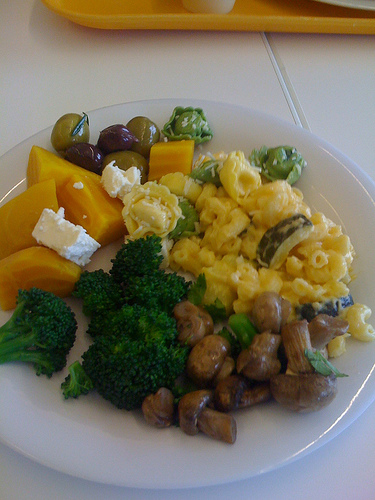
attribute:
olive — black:
[98, 126, 138, 155]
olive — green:
[52, 114, 90, 150]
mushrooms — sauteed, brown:
[141, 292, 353, 443]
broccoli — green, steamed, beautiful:
[2, 233, 193, 411]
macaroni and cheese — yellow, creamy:
[172, 154, 360, 316]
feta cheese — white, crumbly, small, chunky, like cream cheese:
[30, 207, 103, 269]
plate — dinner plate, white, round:
[0, 98, 373, 491]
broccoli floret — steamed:
[1, 288, 78, 379]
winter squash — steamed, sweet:
[0, 140, 197, 313]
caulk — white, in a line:
[261, 33, 301, 128]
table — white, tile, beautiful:
[0, 1, 373, 500]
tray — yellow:
[43, 2, 373, 34]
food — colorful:
[1, 107, 374, 445]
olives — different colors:
[52, 113, 162, 184]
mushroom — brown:
[176, 390, 238, 445]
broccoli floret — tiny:
[61, 361, 93, 399]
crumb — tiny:
[73, 182, 83, 191]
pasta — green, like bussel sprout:
[161, 106, 214, 144]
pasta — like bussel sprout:
[250, 144, 307, 185]